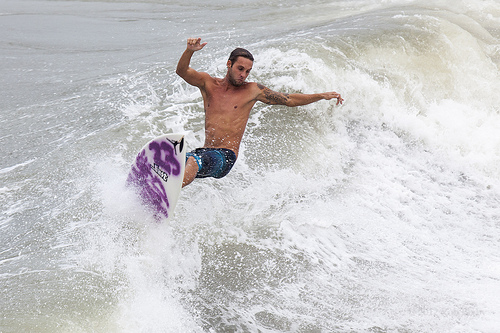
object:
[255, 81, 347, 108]
arm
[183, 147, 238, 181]
shorts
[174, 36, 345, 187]
man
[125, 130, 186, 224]
surfboard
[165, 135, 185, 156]
logo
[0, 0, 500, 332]
water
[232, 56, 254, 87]
face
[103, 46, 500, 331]
wave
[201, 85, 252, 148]
chest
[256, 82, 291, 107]
tattoo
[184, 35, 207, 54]
hand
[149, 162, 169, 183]
emblem